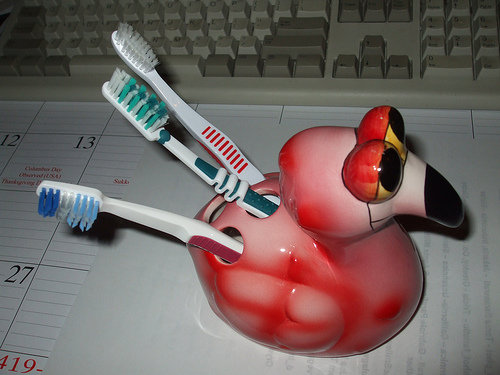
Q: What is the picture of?
A: Toothbrush holder.